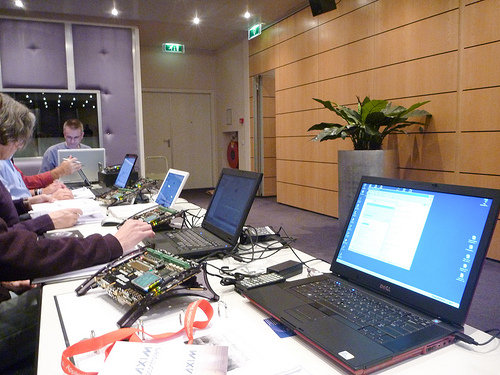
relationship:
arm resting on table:
[1, 222, 123, 282] [37, 181, 499, 373]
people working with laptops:
[1, 91, 153, 278] [47, 144, 198, 231]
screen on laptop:
[335, 181, 493, 308] [235, 173, 496, 373]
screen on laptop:
[203, 174, 256, 236] [144, 165, 264, 256]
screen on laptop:
[114, 157, 136, 187] [87, 153, 139, 196]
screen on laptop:
[156, 170, 186, 209] [107, 166, 192, 221]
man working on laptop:
[38, 118, 98, 177] [50, 146, 109, 184]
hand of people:
[115, 219, 156, 253] [0, 93, 153, 278]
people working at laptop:
[0, 93, 153, 278] [170, 164, 269, 253]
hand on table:
[115, 219, 156, 253] [25, 162, 499, 373]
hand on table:
[49, 209, 81, 229] [25, 162, 499, 373]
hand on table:
[28, 195, 51, 202] [25, 162, 499, 373]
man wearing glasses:
[38, 118, 98, 177] [62, 131, 84, 141]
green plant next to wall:
[308, 95, 433, 150] [241, 2, 498, 264]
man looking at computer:
[38, 118, 98, 177] [54, 147, 109, 183]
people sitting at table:
[1, 91, 153, 278] [37, 181, 499, 373]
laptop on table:
[235, 173, 496, 373] [37, 181, 499, 373]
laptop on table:
[143, 164, 266, 263] [37, 181, 499, 373]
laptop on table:
[107, 166, 192, 221] [37, 181, 499, 373]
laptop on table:
[86, 154, 141, 201] [37, 181, 499, 373]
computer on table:
[56, 147, 108, 183] [37, 181, 499, 373]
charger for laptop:
[267, 257, 330, 280] [235, 173, 496, 373]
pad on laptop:
[285, 291, 336, 328] [235, 173, 496, 373]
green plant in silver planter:
[308, 95, 433, 147] [336, 150, 399, 240]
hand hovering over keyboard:
[114, 213, 157, 256] [114, 205, 235, 266]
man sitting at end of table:
[37, 120, 98, 177] [37, 181, 499, 373]